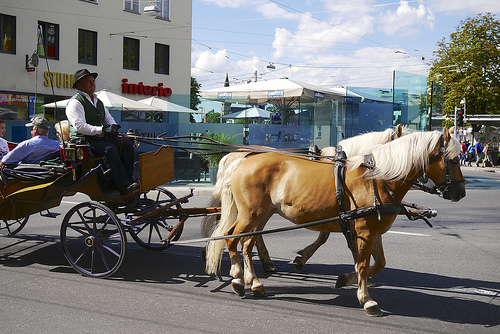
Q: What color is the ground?
A: Gray.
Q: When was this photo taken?
A: During the day.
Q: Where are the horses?
A: On the ground.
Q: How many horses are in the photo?
A: 2.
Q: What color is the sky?
A: Blue.